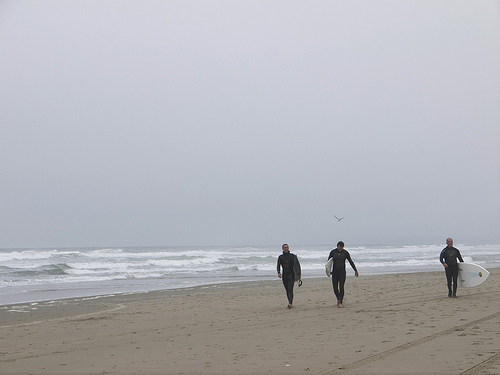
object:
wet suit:
[277, 253, 297, 306]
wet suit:
[330, 247, 354, 301]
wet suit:
[439, 245, 464, 298]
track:
[334, 312, 498, 374]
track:
[476, 362, 497, 375]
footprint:
[325, 358, 338, 366]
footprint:
[355, 348, 363, 356]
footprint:
[381, 337, 394, 346]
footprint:
[402, 328, 415, 336]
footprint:
[404, 321, 414, 324]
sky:
[2, 0, 500, 250]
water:
[0, 244, 495, 306]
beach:
[1, 269, 500, 373]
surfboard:
[292, 257, 298, 282]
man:
[276, 244, 304, 307]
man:
[327, 240, 360, 307]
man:
[439, 235, 463, 299]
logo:
[477, 271, 483, 277]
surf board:
[453, 262, 491, 287]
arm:
[455, 250, 464, 264]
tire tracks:
[331, 301, 498, 373]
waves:
[2, 242, 482, 291]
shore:
[0, 264, 497, 371]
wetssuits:
[276, 252, 302, 307]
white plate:
[333, 215, 344, 223]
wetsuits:
[278, 252, 301, 305]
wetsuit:
[440, 248, 462, 297]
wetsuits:
[443, 246, 462, 295]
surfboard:
[447, 263, 491, 289]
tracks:
[327, 310, 499, 373]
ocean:
[28, 248, 243, 279]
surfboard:
[324, 257, 334, 277]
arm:
[439, 252, 446, 264]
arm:
[347, 252, 358, 272]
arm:
[277, 254, 282, 272]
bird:
[332, 214, 344, 222]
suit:
[277, 243, 301, 306]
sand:
[8, 273, 496, 367]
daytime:
[22, 10, 471, 365]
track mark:
[327, 306, 494, 373]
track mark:
[355, 281, 488, 314]